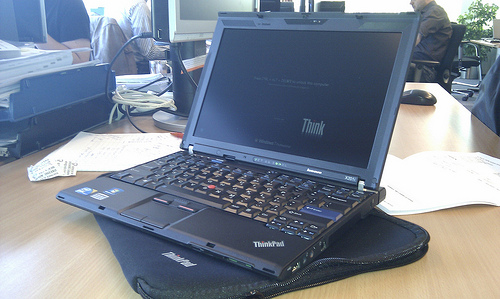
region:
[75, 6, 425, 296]
a laptop on the table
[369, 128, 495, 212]
paper on the table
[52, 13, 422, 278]
a black laptop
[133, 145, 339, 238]
the keyboard of the laptop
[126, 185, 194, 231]
the trackpad of the laptop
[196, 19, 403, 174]
the screen of the laptop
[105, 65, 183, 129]
the cords behind the laptop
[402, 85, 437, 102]
a black computer mouse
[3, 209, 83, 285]
the oak table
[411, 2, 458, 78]
a person sitting in a chair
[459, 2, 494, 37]
a tree in the background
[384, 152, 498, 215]
papers on the desk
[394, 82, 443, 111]
the mouse is black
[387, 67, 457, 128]
the mouse is black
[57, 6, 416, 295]
the laptop is black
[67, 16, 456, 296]
the brand is thinkpad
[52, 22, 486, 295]
a windows laptop on bag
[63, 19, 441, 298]
the laptop is booting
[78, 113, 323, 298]
the bag is black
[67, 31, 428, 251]
the laptop is on a table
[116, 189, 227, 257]
this is a trackpad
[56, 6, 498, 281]
the table is wood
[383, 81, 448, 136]
this is a mouse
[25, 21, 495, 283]
the laptop is alone